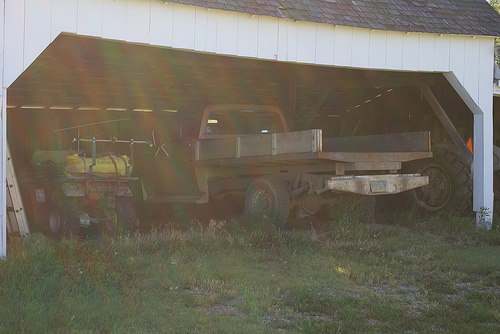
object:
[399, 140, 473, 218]
tire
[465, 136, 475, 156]
triangle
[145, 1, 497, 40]
roof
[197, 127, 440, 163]
bed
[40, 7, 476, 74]
planks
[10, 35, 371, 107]
ceiling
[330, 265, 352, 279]
patch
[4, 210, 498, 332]
ground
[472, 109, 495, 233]
post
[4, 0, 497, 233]
wooden frame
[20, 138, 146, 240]
tractor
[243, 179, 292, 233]
tire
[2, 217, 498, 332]
grass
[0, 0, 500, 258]
barn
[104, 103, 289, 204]
cab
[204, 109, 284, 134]
rear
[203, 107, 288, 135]
window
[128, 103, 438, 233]
cart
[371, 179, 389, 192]
license plate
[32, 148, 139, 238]
tool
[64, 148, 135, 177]
container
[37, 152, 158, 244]
cargo rack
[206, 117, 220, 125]
sticker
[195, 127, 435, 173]
flatbed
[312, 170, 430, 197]
bumper